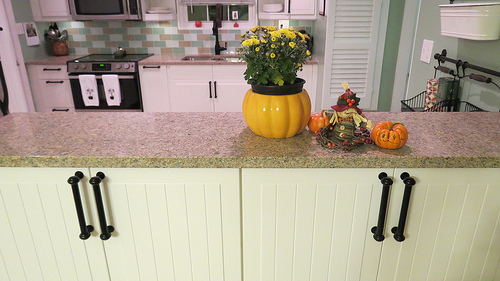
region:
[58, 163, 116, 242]
two black hangers to door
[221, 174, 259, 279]
a small line in between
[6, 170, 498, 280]
two shelfs side by side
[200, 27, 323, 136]
a beautiful jug with flowers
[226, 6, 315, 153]
a jug with green plant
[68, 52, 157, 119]
a big gas stove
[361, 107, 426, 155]
a fruit place on wall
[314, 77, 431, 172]
a group of vegetables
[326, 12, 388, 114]
a beautiful white door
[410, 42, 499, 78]
a small black iron rod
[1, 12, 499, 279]
a beautiful kitchen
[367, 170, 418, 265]
the hardware is black metal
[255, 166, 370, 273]
the doors of the cabinet are white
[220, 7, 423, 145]
this appears to be a Halloween display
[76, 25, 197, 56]
the backsplash is green, brown & white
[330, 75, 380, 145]
this doll has a red hat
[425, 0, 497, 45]
a white metal tub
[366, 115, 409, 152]
a small orange gourd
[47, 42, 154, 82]
a glass top stove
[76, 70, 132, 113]
two hand towels hang on the oven handle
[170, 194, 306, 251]
the drawers are white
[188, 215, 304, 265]
the drawers are white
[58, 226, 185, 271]
the drawers are white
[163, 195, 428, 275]
the drawers are white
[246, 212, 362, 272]
the drawers are white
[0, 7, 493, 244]
a kitchen area decorated for fall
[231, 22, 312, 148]
a yellow-orange pumpkin vase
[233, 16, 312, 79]
a bouquet of flowers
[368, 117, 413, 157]
a mini pumpkin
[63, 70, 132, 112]
two towels on the oven handle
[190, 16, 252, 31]
two red vegetables on the window sill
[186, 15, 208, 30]
a tomato on the window sill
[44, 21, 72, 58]
a container holding cooking spoons and spatulas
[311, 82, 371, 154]
a fall decoration on the counter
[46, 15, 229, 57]
green, white, and brown tiles for the kitchen backsplash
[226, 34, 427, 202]
a yellow pumpkin vase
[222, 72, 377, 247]
a yellow pumpkin vase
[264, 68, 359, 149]
a yellow pumpkin vase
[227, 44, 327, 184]
a yellow pumpkin vase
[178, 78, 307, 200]
a yellow pumpkin vase